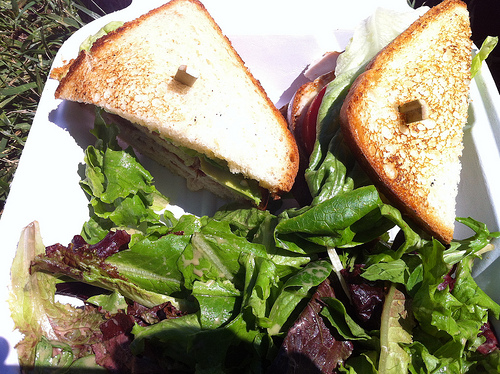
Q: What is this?
A: Food.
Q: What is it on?
A: Plate.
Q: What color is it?
A: Brown.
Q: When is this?
A: Daytime.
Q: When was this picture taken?
A: Daytime.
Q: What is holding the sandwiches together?
A: Sticks.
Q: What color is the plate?
A: White.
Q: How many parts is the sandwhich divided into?
A: 2.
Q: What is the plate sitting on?
A: The grass.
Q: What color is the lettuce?
A: Green and purple.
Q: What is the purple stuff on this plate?
A: Lettuce.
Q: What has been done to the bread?
A: It's Been toasted.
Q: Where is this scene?
A: In a restaurant.